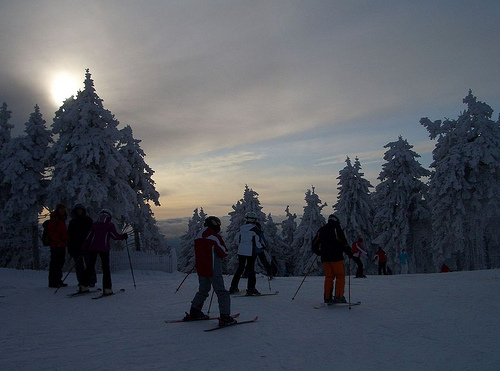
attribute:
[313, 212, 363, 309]
person — skiing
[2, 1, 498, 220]
sky — blue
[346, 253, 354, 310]
ski pole — metal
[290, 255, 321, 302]
ski pole — metal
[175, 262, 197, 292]
ski pole — metal